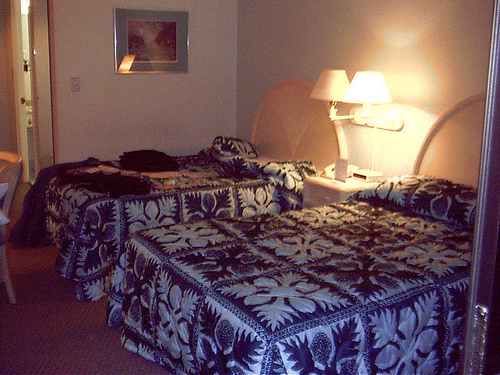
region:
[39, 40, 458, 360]
two double beds in a hotel room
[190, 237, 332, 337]
beds with snowflake design on covers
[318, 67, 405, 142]
two lights above small table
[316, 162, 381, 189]
clock and phone on small table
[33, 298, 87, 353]
carpeting is red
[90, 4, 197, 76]
framed artwork on wall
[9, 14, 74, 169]
bathroom is in the background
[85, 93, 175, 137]
wall looks beige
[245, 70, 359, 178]
white headboard in semicircle shape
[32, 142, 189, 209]
clothes and bags on top of bed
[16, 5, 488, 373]
a bedroom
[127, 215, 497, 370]
a white and blue quilt on a bed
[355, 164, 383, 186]
a white alarm clock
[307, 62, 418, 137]
two white lamps on a wall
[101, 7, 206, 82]
a framed painting on a wall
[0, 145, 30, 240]
seat of a wooden chair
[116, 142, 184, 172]
a black bag on a bed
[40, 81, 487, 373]
two bed side by side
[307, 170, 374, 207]
a white night table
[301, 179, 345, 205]
drawer of a night table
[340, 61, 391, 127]
a brightly lit lamp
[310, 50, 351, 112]
an unlit globe on a double lamp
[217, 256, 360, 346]
a white snowflake on a blue background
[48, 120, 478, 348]
two blue and white beds in a hotel room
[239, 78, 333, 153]
a curved tan headboard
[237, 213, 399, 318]
a blue and white comforter on the bed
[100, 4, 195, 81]
a gold framed picture on the wall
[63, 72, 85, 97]
a beige outlet on the wall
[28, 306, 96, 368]
a brown berber carpet in a hotel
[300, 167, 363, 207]
a light brown bedside table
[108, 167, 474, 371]
a black and white bedspread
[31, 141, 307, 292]
a black and white bedspread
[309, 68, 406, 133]
wall mounted lights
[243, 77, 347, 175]
blonde wood head board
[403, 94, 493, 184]
blonde wood head board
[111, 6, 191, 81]
a framed wall print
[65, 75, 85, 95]
an electric wall switch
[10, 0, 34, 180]
an open bathroom door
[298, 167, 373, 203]
a bedside table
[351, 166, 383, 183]
a white alarm clock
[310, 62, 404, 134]
a wall lamp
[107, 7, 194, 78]
a gray picture frame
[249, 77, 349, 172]
a brown headboard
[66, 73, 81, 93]
a beige light switch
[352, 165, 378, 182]
a white clock radio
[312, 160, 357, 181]
a beige telephone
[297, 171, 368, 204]
a small brown desk table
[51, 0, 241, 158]
a tall white wall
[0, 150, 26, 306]
part of a wooden brown chair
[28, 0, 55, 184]
a tall wall mirror